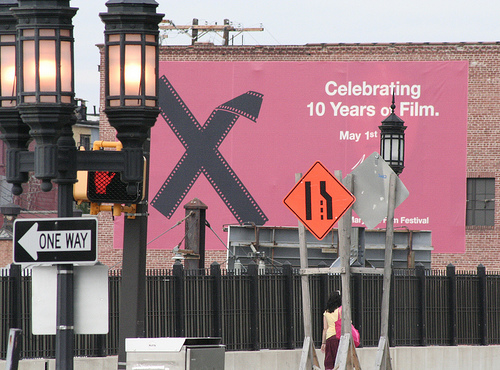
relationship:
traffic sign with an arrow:
[12, 218, 99, 267] [19, 222, 91, 259]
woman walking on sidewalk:
[321, 289, 360, 369] [394, 267, 499, 369]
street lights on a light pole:
[0, 0, 164, 198] [54, 172, 79, 216]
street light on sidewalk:
[381, 91, 409, 174] [394, 267, 499, 369]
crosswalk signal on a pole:
[87, 170, 140, 202] [119, 204, 148, 338]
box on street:
[124, 335, 226, 369] [0, 269, 499, 369]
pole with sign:
[297, 239, 395, 369] [283, 159, 355, 240]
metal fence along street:
[394, 262, 500, 344] [0, 269, 499, 369]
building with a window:
[160, 46, 500, 270] [467, 177, 497, 230]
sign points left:
[12, 218, 99, 267] [19, 222, 91, 259]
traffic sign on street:
[12, 218, 99, 267] [0, 269, 499, 369]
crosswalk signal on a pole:
[77, 170, 147, 217] [119, 204, 148, 338]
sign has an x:
[159, 59, 469, 253] [152, 73, 268, 228]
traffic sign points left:
[19, 222, 91, 259] [19, 222, 91, 259]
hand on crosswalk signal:
[92, 170, 118, 198] [87, 170, 140, 202]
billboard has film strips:
[159, 59, 469, 253] [150, 71, 269, 224]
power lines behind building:
[164, 16, 266, 45] [98, 43, 499, 274]